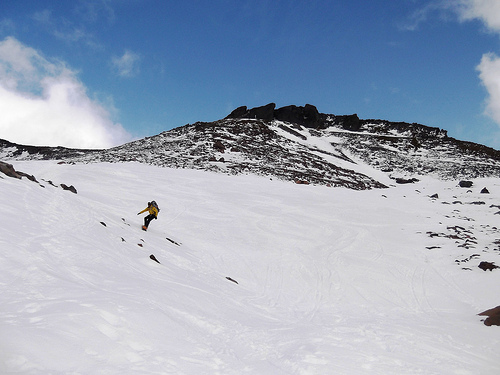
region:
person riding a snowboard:
[132, 199, 163, 234]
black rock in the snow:
[60, 179, 80, 196]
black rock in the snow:
[94, 219, 107, 229]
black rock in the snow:
[118, 214, 130, 224]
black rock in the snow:
[145, 250, 162, 265]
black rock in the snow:
[116, 232, 129, 242]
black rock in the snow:
[225, 270, 240, 281]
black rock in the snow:
[165, 233, 181, 244]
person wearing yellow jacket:
[131, 196, 164, 234]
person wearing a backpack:
[132, 196, 159, 236]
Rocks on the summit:
[245, 109, 305, 116]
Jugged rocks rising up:
[240, 103, 317, 113]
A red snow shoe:
[140, 224, 147, 231]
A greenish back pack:
[151, 200, 156, 207]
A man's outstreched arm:
[137, 210, 147, 215]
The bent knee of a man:
[143, 215, 148, 221]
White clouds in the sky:
[3, 100, 48, 128]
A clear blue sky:
[225, 13, 290, 45]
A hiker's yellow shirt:
[149, 206, 156, 213]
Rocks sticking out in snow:
[440, 225, 479, 244]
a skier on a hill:
[129, 188, 170, 238]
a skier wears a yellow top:
[128, 191, 164, 238]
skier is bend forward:
[129, 195, 168, 237]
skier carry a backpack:
[132, 193, 164, 235]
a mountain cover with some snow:
[111, 90, 498, 190]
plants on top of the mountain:
[173, 90, 495, 152]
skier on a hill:
[81, 176, 285, 356]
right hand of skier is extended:
[128, 195, 164, 235]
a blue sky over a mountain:
[5, 13, 497, 373]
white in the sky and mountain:
[7, 70, 132, 228]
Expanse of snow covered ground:
[10, 185, 468, 370]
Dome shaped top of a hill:
[113, 83, 498, 181]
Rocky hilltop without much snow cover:
[115, 91, 499, 186]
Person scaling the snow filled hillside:
[135, 197, 163, 231]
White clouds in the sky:
[0, 55, 128, 150]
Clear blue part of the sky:
[102, 58, 475, 116]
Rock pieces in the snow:
[83, 204, 246, 298]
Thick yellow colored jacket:
[138, 205, 163, 215]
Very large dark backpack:
[151, 193, 162, 212]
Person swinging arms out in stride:
[136, 206, 161, 221]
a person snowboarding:
[127, 190, 177, 252]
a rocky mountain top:
[172, 95, 481, 200]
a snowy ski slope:
[42, 151, 452, 370]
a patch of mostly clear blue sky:
[41, 14, 450, 110]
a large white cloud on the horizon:
[9, 66, 102, 149]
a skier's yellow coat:
[133, 206, 163, 216]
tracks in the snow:
[284, 207, 383, 324]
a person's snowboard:
[132, 220, 154, 237]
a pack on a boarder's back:
[150, 199, 162, 212]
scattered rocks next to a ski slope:
[447, 196, 494, 320]